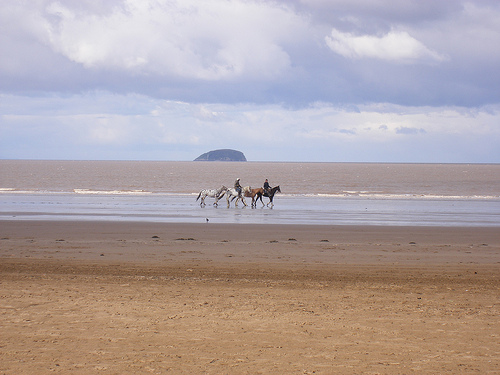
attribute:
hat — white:
[235, 173, 243, 183]